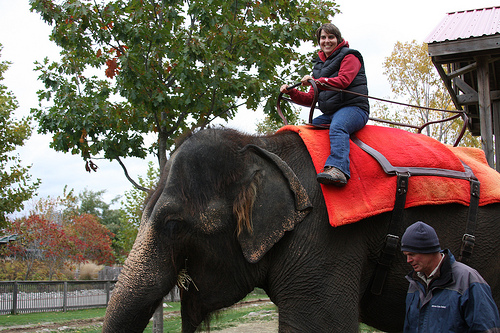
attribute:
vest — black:
[309, 63, 349, 112]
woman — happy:
[313, 25, 343, 59]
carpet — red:
[355, 123, 499, 207]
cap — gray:
[393, 222, 450, 255]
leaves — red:
[25, 219, 115, 262]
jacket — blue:
[397, 270, 490, 329]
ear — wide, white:
[235, 146, 317, 270]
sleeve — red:
[321, 60, 360, 100]